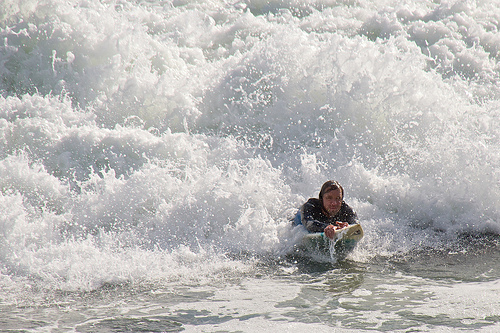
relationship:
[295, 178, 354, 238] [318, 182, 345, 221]
man has head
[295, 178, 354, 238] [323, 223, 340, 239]
man has hand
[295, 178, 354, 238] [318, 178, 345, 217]
man has hair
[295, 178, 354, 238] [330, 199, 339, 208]
man has nose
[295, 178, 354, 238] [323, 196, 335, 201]
man has eye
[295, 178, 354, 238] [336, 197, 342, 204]
man has eye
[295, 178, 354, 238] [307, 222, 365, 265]
man on top of surfboard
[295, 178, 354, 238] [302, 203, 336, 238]
man has arm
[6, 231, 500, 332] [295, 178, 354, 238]
water in front of man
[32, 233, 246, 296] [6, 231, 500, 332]
splashes are on water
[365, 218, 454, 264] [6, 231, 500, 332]
splashes are on water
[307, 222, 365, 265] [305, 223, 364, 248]
surfboard has edge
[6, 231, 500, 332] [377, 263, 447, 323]
water has part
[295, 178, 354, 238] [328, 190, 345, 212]
man has face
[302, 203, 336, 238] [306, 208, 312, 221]
arm has part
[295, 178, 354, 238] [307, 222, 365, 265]
man lying on top of surfboard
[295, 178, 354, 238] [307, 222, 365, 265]
man gripping surfboard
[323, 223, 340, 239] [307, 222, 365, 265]
hand gripping surfboard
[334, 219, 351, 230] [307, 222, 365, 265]
hand gripping surfboard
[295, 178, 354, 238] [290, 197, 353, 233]
man wearing wetsuit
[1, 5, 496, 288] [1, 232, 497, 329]
wave breaking on sand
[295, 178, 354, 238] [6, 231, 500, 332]
man in water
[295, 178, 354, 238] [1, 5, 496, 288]
man surfing in wave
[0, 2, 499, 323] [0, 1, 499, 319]
picture during daytime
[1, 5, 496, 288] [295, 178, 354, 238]
wave behind man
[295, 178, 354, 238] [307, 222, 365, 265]
man holding surfboard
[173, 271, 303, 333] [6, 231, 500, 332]
sud on water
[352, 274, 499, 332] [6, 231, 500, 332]
sud on water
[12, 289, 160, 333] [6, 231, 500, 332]
sud on water